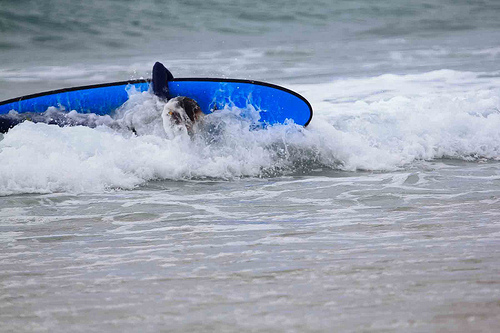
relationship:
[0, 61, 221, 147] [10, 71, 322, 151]
person fell off surfboard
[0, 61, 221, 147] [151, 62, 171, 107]
person wearing shirt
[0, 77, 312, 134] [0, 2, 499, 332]
board in water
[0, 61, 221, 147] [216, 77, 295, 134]
person falling off of surfboard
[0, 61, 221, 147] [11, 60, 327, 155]
person riding surfboard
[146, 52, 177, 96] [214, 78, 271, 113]
person's arm hanging over surfboard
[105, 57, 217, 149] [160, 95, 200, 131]
person has dark hair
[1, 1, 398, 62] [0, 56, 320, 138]
waves behind surfboard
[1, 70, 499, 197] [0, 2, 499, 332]
spray on water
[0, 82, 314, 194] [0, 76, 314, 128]
water on surfboard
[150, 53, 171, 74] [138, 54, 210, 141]
elbow of person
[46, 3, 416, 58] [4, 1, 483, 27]
clouds in sky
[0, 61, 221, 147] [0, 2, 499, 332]
person under water